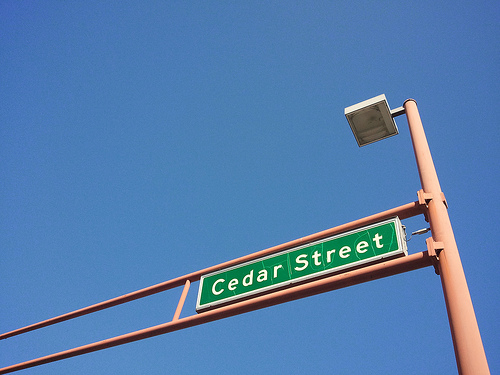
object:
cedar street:
[211, 232, 384, 295]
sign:
[195, 217, 403, 312]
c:
[211, 279, 225, 296]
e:
[227, 278, 238, 291]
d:
[242, 269, 253, 287]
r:
[273, 264, 283, 278]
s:
[294, 253, 309, 271]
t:
[312, 250, 322, 265]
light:
[344, 94, 400, 148]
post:
[402, 98, 492, 375]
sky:
[0, 0, 500, 375]